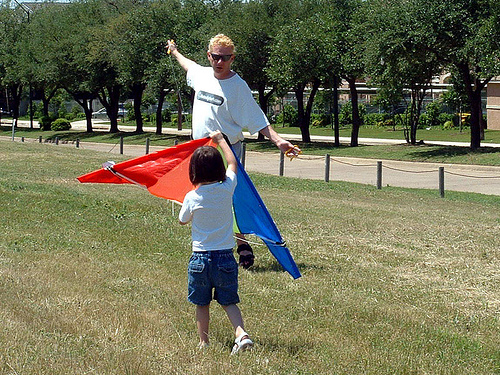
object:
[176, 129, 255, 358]
girl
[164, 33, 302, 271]
man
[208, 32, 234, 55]
hair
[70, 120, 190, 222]
kite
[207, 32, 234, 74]
head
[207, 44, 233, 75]
face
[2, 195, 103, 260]
grass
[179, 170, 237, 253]
shirt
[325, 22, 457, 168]
tree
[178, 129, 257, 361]
child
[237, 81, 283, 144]
arm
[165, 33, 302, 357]
people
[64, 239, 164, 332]
ground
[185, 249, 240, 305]
short